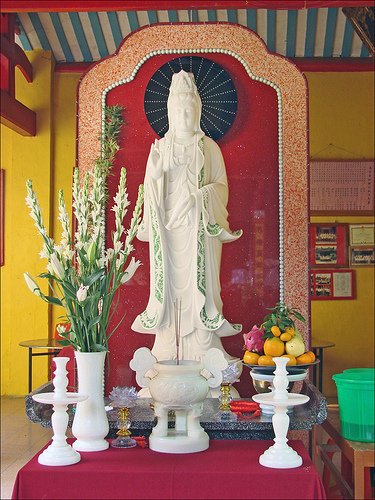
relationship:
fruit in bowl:
[296, 349, 316, 367] [243, 362, 320, 373]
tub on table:
[333, 368, 374, 440] [307, 402, 374, 499]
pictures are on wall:
[309, 157, 373, 301] [0, 52, 374, 393]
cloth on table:
[14, 435, 326, 498] [10, 434, 322, 498]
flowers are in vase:
[26, 107, 146, 350] [73, 348, 110, 455]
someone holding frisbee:
[132, 71, 242, 364] [165, 194, 192, 230]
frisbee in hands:
[165, 194, 192, 230] [167, 192, 196, 227]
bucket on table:
[333, 368, 374, 440] [307, 402, 374, 499]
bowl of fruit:
[243, 362, 320, 373] [241, 318, 318, 365]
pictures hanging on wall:
[309, 157, 373, 301] [0, 52, 374, 393]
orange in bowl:
[264, 336, 284, 357] [243, 362, 320, 373]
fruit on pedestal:
[241, 318, 318, 365] [249, 369, 309, 406]